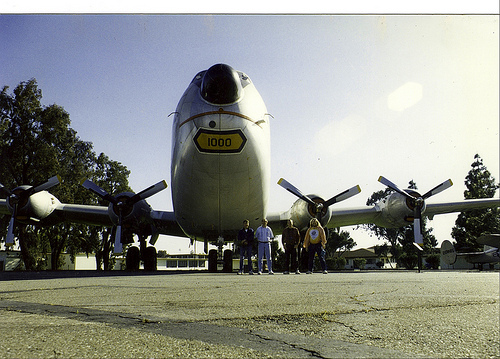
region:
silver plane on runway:
[3, 62, 498, 269]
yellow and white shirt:
[305, 225, 326, 246]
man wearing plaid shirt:
[281, 219, 301, 273]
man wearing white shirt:
[256, 218, 274, 274]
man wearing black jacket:
[238, 218, 255, 273]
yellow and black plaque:
[192, 125, 248, 157]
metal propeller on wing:
[375, 173, 454, 250]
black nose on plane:
[201, 63, 243, 105]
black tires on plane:
[126, 245, 157, 274]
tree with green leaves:
[1, 76, 67, 275]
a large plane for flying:
[7, 27, 480, 332]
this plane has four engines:
[9, 160, 452, 253]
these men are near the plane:
[234, 203, 339, 278]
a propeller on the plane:
[377, 161, 457, 247]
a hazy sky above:
[272, 29, 472, 168]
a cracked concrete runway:
[7, 269, 488, 356]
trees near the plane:
[7, 84, 125, 189]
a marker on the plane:
[179, 112, 271, 164]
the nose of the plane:
[179, 49, 265, 110]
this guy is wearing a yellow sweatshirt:
[299, 214, 334, 271]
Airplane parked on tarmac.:
[1, 59, 498, 271]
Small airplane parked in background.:
[440, 233, 497, 268]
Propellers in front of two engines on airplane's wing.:
[2, 167, 174, 255]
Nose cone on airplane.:
[196, 63, 246, 108]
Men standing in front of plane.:
[231, 213, 338, 277]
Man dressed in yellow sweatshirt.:
[299, 223, 335, 250]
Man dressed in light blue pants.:
[254, 239, 275, 274]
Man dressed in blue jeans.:
[234, 243, 256, 272]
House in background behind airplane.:
[330, 240, 401, 275]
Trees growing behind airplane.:
[6, 125, 131, 273]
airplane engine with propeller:
[376, 172, 448, 249]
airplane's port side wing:
[269, 196, 499, 226]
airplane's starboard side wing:
[0, 200, 172, 233]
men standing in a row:
[237, 210, 334, 274]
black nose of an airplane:
[201, 65, 242, 104]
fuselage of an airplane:
[169, 149, 273, 243]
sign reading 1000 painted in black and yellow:
[194, 127, 249, 152]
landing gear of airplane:
[126, 231, 161, 275]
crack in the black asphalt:
[247, 323, 327, 353]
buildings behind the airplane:
[70, 247, 430, 272]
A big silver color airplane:
[1, 38, 493, 357]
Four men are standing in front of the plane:
[232, 215, 337, 307]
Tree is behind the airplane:
[2, 15, 293, 352]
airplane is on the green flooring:
[5, 50, 491, 321]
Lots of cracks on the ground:
[235, 298, 448, 351]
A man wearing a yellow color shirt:
[298, 205, 344, 282]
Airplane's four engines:
[7, 167, 493, 260]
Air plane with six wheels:
[108, 240, 353, 281]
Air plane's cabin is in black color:
[170, 56, 266, 172]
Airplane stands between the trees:
[18, 48, 491, 298]